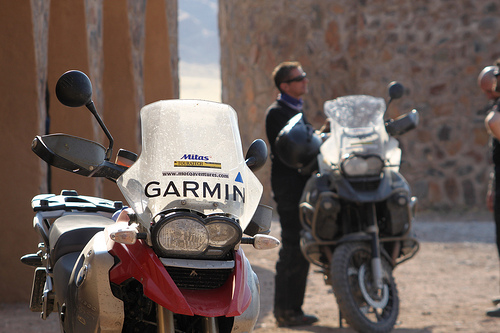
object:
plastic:
[114, 98, 265, 233]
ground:
[3, 197, 496, 327]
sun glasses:
[280, 71, 307, 83]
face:
[287, 65, 309, 97]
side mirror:
[53, 69, 116, 161]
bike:
[273, 80, 420, 332]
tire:
[327, 240, 400, 333]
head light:
[203, 216, 243, 248]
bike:
[20, 57, 290, 327]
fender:
[110, 239, 252, 317]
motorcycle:
[18, 69, 281, 333]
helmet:
[274, 111, 321, 176]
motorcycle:
[271, 81, 421, 332]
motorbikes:
[19, 69, 420, 333]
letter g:
[144, 181, 161, 198]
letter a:
[163, 181, 181, 197]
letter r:
[183, 180, 200, 197]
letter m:
[202, 181, 221, 199]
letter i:
[225, 184, 230, 201]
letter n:
[233, 185, 246, 204]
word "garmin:
[144, 180, 246, 203]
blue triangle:
[233, 171, 245, 183]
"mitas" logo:
[173, 152, 223, 169]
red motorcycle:
[106, 232, 252, 317]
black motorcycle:
[274, 81, 421, 332]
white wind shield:
[115, 99, 262, 230]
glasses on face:
[282, 74, 306, 82]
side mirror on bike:
[28, 130, 108, 179]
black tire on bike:
[325, 241, 400, 332]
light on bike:
[156, 212, 211, 255]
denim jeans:
[272, 192, 310, 315]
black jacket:
[264, 93, 312, 209]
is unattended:
[19, 69, 282, 333]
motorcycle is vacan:
[20, 69, 280, 333]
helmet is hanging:
[476, 65, 499, 98]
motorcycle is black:
[296, 165, 417, 333]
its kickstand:
[19, 69, 282, 333]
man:
[262, 61, 319, 327]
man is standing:
[262, 62, 321, 330]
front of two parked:
[327, 240, 401, 333]